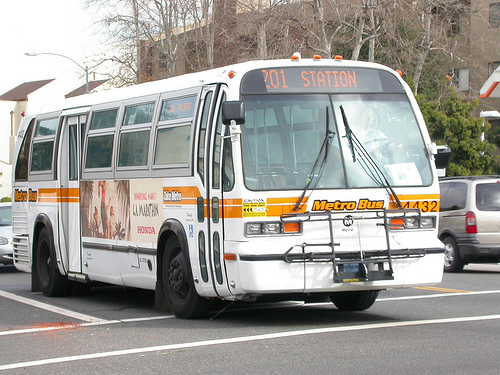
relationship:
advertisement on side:
[80, 181, 163, 247] [17, 72, 235, 296]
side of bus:
[17, 72, 235, 296] [12, 58, 447, 318]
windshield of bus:
[239, 92, 434, 188] [12, 58, 447, 318]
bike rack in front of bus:
[280, 205, 426, 284] [12, 58, 447, 318]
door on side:
[194, 85, 224, 297] [17, 72, 235, 296]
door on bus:
[194, 85, 224, 297] [12, 58, 447, 318]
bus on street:
[12, 58, 447, 318] [0, 208, 496, 374]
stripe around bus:
[15, 187, 445, 222] [12, 58, 447, 318]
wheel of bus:
[31, 227, 63, 292] [12, 58, 447, 318]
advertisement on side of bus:
[80, 181, 163, 247] [12, 58, 447, 318]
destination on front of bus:
[300, 69, 360, 90] [12, 58, 447, 318]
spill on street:
[29, 319, 84, 337] [0, 208, 496, 374]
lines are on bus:
[223, 192, 434, 217] [12, 58, 447, 318]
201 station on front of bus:
[260, 68, 360, 89] [12, 58, 447, 318]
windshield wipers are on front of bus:
[296, 103, 402, 211] [12, 58, 447, 318]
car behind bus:
[1, 200, 14, 269] [12, 58, 447, 318]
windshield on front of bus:
[239, 92, 434, 188] [12, 58, 447, 318]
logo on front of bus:
[310, 198, 384, 210] [12, 58, 447, 318]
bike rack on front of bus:
[280, 205, 426, 284] [12, 58, 447, 318]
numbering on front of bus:
[403, 201, 437, 213] [12, 58, 447, 318]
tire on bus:
[162, 236, 206, 318] [12, 58, 447, 318]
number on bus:
[261, 70, 288, 90] [12, 58, 447, 318]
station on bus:
[300, 69, 360, 90] [12, 58, 447, 318]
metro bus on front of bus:
[310, 198, 384, 210] [12, 58, 447, 318]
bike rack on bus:
[280, 205, 426, 284] [12, 58, 447, 318]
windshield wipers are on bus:
[296, 103, 402, 211] [12, 58, 447, 318]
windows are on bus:
[37, 103, 191, 174] [12, 58, 447, 318]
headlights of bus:
[242, 219, 434, 231] [12, 58, 447, 318]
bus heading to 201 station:
[12, 58, 447, 318] [256, 64, 361, 92]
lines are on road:
[223, 192, 434, 217] [0, 208, 496, 374]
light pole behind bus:
[24, 48, 113, 93] [12, 58, 447, 318]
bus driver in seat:
[350, 104, 392, 171] [322, 141, 396, 183]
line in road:
[414, 284, 467, 297] [0, 208, 496, 374]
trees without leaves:
[92, 0, 449, 89] [420, 89, 494, 177]